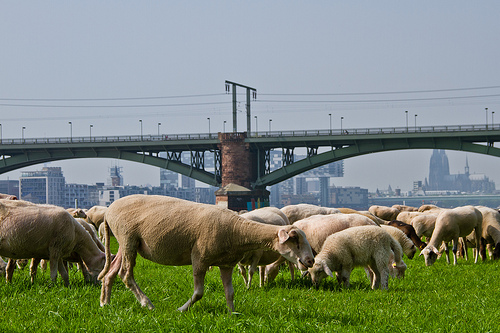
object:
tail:
[97, 215, 111, 281]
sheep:
[400, 211, 438, 241]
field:
[262, 286, 490, 330]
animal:
[418, 205, 486, 265]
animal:
[0, 204, 117, 283]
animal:
[258, 212, 382, 287]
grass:
[1, 235, 498, 332]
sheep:
[84, 204, 111, 228]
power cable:
[2, 93, 498, 110]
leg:
[114, 235, 153, 308]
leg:
[99, 233, 125, 308]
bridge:
[1, 79, 500, 211]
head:
[272, 221, 314, 273]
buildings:
[371, 147, 499, 202]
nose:
[299, 256, 314, 268]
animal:
[95, 187, 316, 312]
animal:
[307, 224, 415, 289]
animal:
[464, 202, 499, 261]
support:
[213, 130, 499, 212]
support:
[0, 142, 274, 212]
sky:
[246, 8, 426, 74]